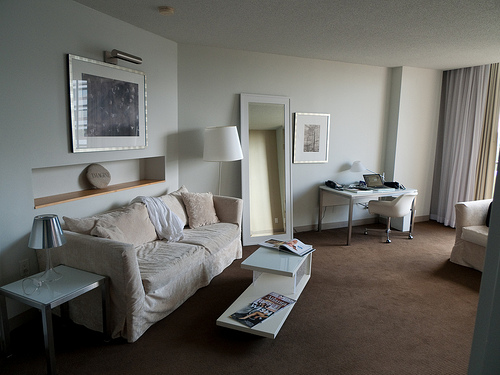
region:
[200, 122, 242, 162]
White lampshade in a room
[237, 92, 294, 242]
A mirror in a room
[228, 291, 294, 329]
A poster on a table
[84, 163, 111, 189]
A decoration in a room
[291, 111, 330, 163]
A picture frame on a wall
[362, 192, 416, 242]
A chair in a room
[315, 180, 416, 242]
A table in a room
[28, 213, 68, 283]
A silver lamp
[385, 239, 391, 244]
A wheel on a leg of a chair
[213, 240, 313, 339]
A coffee table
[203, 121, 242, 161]
a white lampshade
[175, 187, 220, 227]
a beige pillow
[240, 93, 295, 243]
a long white mirror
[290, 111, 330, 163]
a wall picture frame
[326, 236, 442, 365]
part of a brown carpet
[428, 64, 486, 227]
long white curtains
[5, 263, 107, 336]
an end table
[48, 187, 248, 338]
a long beige sofa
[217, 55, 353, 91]
part of a white painted wall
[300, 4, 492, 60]
part of a white ceiling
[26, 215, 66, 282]
lamp on the table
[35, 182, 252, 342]
couch in front of coffee table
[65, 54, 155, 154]
painting hanging on wall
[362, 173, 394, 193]
laptop on the desk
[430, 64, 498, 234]
curtain hanging from window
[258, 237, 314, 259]
magazine on the coffee table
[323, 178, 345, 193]
telephone on the desk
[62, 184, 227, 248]
four cushions on the sofa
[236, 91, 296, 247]
mirror next to lamp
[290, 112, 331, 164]
painting on wall next to mirror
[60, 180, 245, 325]
couch in the livingroom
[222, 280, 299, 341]
magazines on the stand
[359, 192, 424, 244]
white chair near the desk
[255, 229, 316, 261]
opened book on the stand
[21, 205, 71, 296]
lamp on the stand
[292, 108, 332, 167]
picture in the wall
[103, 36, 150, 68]
lamp on the wall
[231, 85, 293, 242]
mirror on the wall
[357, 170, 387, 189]
laptop on the desk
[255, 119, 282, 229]
reflection in the mirror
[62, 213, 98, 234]
the fluffy cream cushion on the couch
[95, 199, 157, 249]
the fluffy cream cushion on the couch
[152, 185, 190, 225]
the fluffy cream cushion on the couch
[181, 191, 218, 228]
the fluffy cream cushion on the couch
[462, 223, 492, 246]
the fluffy cream cushion on the couch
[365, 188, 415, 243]
the cream colored chair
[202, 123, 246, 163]
the white lamp shade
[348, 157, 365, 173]
the white lamp shade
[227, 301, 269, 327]
the magazine on the table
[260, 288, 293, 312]
the magazine on the table